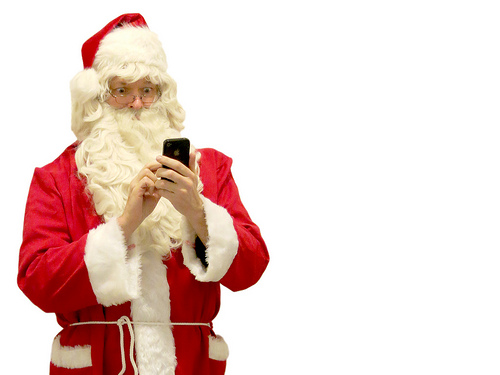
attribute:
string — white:
[112, 308, 139, 374]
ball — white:
[68, 68, 101, 100]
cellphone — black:
[162, 138, 188, 185]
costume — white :
[16, 12, 269, 373]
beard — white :
[75, 96, 204, 261]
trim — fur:
[201, 337, 228, 362]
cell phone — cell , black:
[162, 132, 204, 196]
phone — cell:
[164, 135, 193, 176]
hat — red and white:
[66, 0, 173, 80]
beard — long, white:
[80, 99, 188, 259]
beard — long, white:
[53, 115, 177, 199]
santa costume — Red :
[16, 8, 269, 373]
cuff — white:
[85, 216, 143, 309]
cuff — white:
[181, 195, 238, 282]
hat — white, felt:
[76, 9, 168, 71]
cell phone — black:
[161, 139, 188, 181]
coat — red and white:
[63, 177, 205, 303]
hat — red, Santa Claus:
[71, 14, 173, 82]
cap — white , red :
[71, 0, 193, 90]